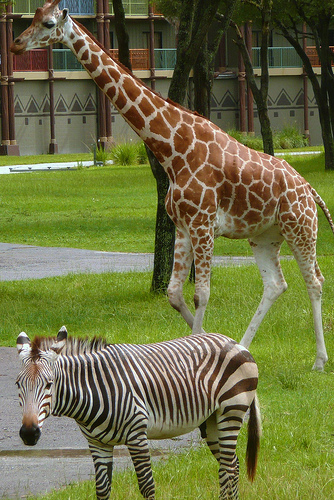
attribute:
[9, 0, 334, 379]
giraffe — big, full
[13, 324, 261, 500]
zebra — black, curious, striped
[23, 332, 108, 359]
mane — straight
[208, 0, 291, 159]
tree — green, mossy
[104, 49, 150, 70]
railing — orange, colorful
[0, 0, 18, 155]
pole — tall, wooden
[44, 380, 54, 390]
eye — large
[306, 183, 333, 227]
tail — fluffy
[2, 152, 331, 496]
grass — overgrown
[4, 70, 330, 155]
wall — designed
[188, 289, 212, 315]
knee — skinny